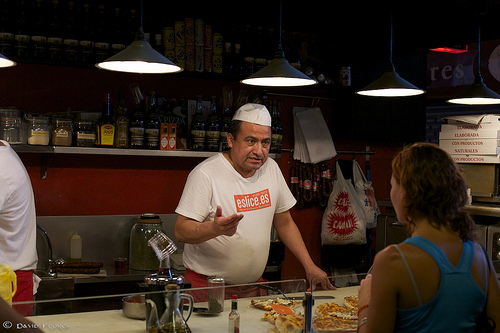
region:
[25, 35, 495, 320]
A man is working in a restaurant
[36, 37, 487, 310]
A man is talking to a customer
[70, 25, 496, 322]
A customer is ordering some food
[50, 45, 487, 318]
A cook is working in a restaurant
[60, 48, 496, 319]
A cook is preparing somebody's lunch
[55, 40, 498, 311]
A restaurant owner is chatting with someone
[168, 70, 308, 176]
A man is wearing a white hat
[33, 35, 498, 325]
A restaurant is open for business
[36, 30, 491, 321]
The restaurant is serving good food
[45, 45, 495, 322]
A restaurant worker is getting an order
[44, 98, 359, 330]
man standing behind a counter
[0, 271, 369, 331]
glass shield in front of counter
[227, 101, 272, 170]
man wearing a small white paper hat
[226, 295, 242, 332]
a small chili bottle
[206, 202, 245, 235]
man gesturing with his right hand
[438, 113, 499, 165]
stacked pizza boxes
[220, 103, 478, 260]
man looking towards female customer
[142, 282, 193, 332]
bottle with handle and spout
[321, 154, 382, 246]
plastic bags hung near wall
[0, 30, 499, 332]
large lights hung above counter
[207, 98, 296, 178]
head of a man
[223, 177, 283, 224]
orange and white symbol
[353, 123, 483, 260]
head of a girl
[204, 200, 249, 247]
hand of a man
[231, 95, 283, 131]
hat on man's head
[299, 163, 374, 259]
bags behind the man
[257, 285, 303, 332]
food on the table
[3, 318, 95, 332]
name in bottom left corner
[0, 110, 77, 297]
back of a person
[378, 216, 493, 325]
blue shirt on lady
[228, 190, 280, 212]
word on the man shirt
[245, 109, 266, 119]
man is wearing a white hat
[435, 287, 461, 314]
lady is wearing a blue tank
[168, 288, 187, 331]
clear glass bottle on the table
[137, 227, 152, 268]
clear glass jar on the counter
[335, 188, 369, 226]
white bags hanging off the hook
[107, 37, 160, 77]
light hanging from the top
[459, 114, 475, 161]
boxes stacked on the shelf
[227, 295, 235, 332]
bottle of hot sauce on the table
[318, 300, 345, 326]
pizza sliced up on the table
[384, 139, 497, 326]
A lady ordering pizza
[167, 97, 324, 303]
Pizza man talking to a customer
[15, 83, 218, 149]
a shelf holding different spices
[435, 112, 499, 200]
Pizza boxes waiting to be filled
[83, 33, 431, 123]
Lights hanging over the order area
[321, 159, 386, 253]
Grocery bags to help customers with their orders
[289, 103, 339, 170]
Order sheets hanging on the wall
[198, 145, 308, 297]
White t-shirt with pizza shop logo on it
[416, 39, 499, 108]
Part of a neon sign that shows to the outside of shop hanging in window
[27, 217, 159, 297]
Sink and prep area to make it easier